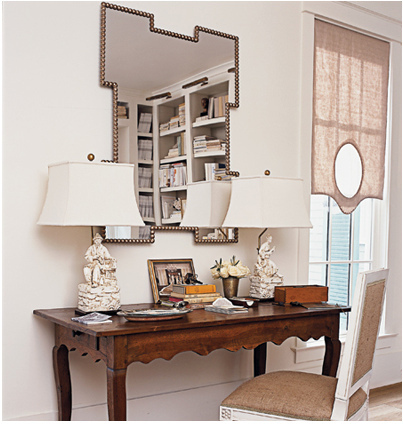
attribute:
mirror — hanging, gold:
[96, 1, 239, 247]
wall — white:
[1, 2, 308, 424]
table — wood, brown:
[34, 303, 353, 423]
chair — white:
[221, 270, 390, 421]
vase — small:
[208, 255, 247, 301]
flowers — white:
[205, 256, 249, 277]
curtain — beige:
[310, 17, 389, 218]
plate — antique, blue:
[120, 300, 197, 323]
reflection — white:
[123, 75, 228, 243]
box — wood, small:
[277, 284, 328, 306]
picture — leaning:
[145, 259, 200, 305]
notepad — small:
[74, 310, 111, 325]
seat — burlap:
[223, 366, 368, 417]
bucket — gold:
[224, 275, 243, 294]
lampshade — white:
[38, 158, 144, 228]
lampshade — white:
[217, 169, 315, 233]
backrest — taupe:
[333, 262, 388, 407]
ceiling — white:
[358, 1, 402, 29]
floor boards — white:
[0, 342, 402, 424]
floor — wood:
[358, 381, 398, 421]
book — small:
[208, 297, 245, 316]